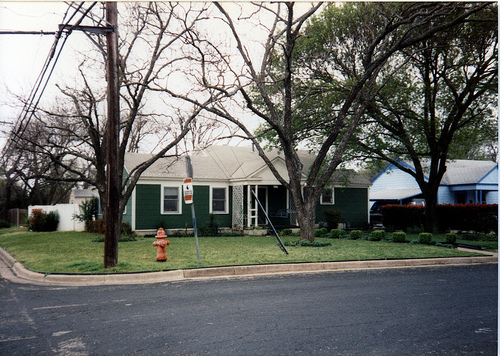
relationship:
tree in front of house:
[251, 1, 498, 231] [368, 154, 498, 226]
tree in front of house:
[0, 0, 258, 270] [98, 145, 373, 237]